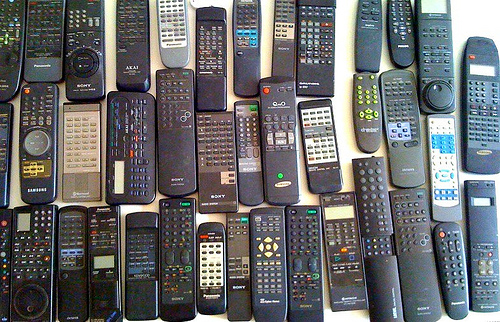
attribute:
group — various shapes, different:
[65, 46, 420, 280]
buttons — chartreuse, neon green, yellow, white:
[358, 82, 382, 136]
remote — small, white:
[348, 67, 388, 154]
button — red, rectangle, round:
[262, 83, 275, 100]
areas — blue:
[431, 133, 456, 201]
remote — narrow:
[272, 3, 301, 79]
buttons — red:
[122, 122, 137, 164]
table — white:
[336, 1, 499, 196]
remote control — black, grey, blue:
[232, 6, 271, 94]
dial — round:
[422, 78, 454, 115]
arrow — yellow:
[257, 240, 267, 256]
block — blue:
[435, 184, 462, 208]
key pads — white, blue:
[431, 119, 452, 189]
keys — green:
[358, 79, 377, 123]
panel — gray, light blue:
[161, 8, 185, 43]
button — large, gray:
[25, 126, 51, 155]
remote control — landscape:
[107, 86, 158, 201]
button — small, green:
[276, 168, 286, 181]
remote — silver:
[155, 0, 195, 63]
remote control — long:
[350, 150, 410, 321]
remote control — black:
[158, 198, 199, 320]